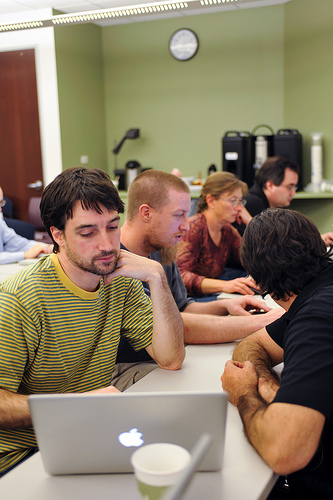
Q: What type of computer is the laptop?
A: Apple.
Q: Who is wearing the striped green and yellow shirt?
A: The man next to the computer.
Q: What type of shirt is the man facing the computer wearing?
A: A green and yellow striped shirt.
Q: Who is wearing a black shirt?
A: The man next to the computer.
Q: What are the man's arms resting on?
A: The table.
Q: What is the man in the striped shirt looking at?
A: The computer.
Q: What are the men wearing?
A: T shirts.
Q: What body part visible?
A: Arm.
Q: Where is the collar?
A: Shirt.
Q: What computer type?
A: Laptop.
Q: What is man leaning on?
A: Hand.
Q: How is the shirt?
A: Striped.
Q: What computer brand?
A: Apple.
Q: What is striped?
A: Shirt.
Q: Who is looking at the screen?
A: The man in the yellow shirt.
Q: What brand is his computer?
A: Apple.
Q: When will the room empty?
A: At the end of the workshop.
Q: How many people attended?
A: At least 6.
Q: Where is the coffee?
A: Near the wall.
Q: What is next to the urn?
A: Stacks of cups.